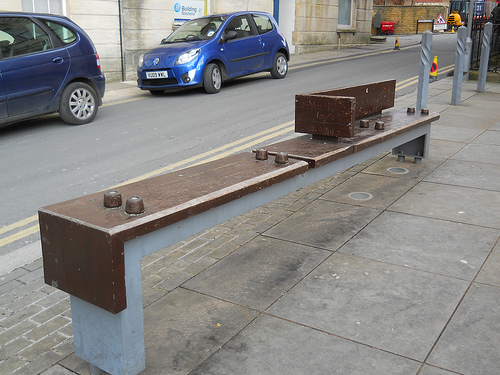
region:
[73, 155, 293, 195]
a bench on the side of the road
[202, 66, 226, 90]
the front wheel of a car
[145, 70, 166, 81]
the number plate of a car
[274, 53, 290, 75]
the rear wheel of a car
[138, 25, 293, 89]
a car parked a long the road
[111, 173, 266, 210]
a wooden top of a bench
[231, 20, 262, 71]
the door of a car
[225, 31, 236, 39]
the side mirror of a car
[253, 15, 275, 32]
the window of a car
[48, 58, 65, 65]
the handle of a door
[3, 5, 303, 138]
two blue cars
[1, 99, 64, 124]
dirt on the bottom of the car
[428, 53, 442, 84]
cone on the road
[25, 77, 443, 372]
slanted brown and white bench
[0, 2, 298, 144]
two cars parked on the side of the road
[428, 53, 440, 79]
yellow, red, and black cone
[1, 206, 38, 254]
two parallel lines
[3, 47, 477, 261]
lines on the side of the road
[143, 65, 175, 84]
white and black license plate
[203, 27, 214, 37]
sticker in the window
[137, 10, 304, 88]
small blue car on street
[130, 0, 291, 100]
blue car parked at curb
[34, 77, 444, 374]
long bench in multiple materials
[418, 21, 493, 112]
short poles in sidewalk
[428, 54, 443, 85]
yellow cone in street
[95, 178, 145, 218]
brown knobs on bench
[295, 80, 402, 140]
seat back on bench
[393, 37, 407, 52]
yellow cone on other side of the street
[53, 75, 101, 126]
rear tire of small blue car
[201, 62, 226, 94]
front tire of small blue car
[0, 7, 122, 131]
this is a car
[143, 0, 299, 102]
this is a car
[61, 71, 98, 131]
this is a wheel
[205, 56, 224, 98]
this is a wheel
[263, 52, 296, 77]
this is a wheel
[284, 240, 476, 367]
this is a block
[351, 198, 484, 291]
this is a block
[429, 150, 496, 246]
this is a block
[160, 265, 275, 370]
this is a block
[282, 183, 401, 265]
this is a block